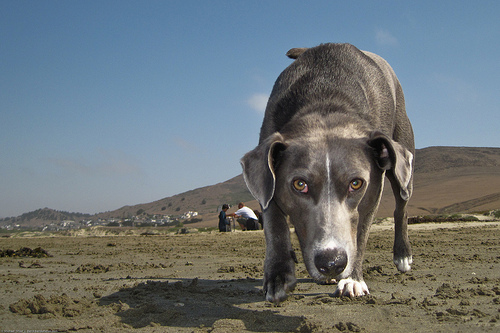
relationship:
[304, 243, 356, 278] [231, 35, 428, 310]
nose of dog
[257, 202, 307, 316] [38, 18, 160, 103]
legs in air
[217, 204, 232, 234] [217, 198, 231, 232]
person a child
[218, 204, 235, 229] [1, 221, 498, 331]
person sitting on beach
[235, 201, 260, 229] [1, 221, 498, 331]
person sitting on beach